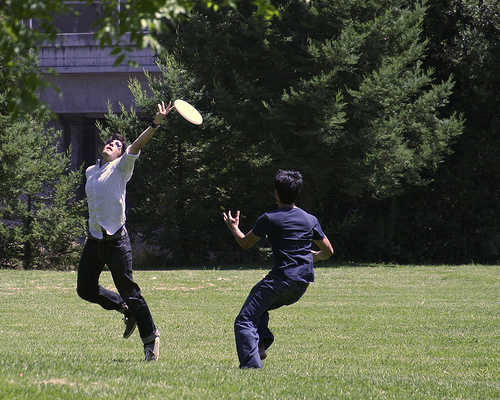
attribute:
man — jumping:
[67, 104, 165, 361]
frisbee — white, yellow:
[171, 96, 205, 128]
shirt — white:
[78, 146, 141, 238]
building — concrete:
[6, 0, 186, 134]